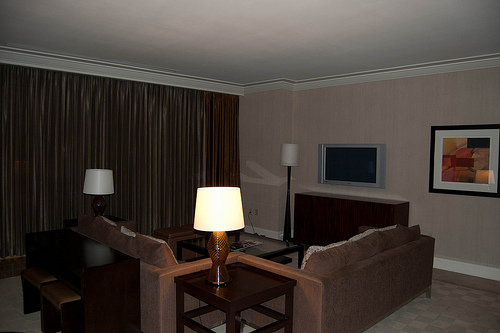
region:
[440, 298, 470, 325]
Part of the ground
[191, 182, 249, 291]
A light on the table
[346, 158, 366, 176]
Part of the TV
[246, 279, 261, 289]
Part of the table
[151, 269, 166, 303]
Part of the couch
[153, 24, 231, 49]
Part of the ceiling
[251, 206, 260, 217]
A power outlet on the wall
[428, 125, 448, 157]
Part of the picture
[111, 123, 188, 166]
Part of the curtain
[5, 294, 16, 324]
Part of the carpet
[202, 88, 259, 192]
blinds of a window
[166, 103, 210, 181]
blinds of a window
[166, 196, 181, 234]
blinds of a window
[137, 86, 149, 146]
blinds of a window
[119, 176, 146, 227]
blinds of a window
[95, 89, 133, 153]
blinds of a window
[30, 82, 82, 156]
blinds of a window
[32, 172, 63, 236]
blinds of a window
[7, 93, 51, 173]
blinds of a window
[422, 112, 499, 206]
picture frame on the wall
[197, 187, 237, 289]
lamp on the table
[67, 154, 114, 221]
lamp on the table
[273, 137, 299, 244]
lamp on the floor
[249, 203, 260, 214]
outlet on the wall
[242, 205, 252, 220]
outlet on the wall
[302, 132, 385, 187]
tv on the wall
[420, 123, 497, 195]
picture on the wall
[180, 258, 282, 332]
table by the couch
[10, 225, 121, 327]
table behind the couch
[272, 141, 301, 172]
shade on the lamp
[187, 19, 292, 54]
The ceiling is white.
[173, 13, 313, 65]
The ceiling is smooth.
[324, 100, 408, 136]
The wall is biege.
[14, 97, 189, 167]
The curtains are brown.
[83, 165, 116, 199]
The lamp shade is white.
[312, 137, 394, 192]
The television is on the wall.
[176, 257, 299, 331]
The end table is brown.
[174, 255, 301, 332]
The end table is made of wood.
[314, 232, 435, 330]
The sofa is brown in color.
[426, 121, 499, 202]
The picture frame is dark in color.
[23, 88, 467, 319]
a living room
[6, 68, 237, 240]
curtains on the window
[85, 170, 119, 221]
a lamp on the table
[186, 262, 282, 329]
a wooden end table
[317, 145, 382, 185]
a television on the wall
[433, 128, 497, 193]
a picture on the wall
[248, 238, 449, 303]
a couch in the living room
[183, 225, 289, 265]
a coffee table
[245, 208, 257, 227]
a cord plugged into the wall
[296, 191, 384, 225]
a wooden dresser under the television